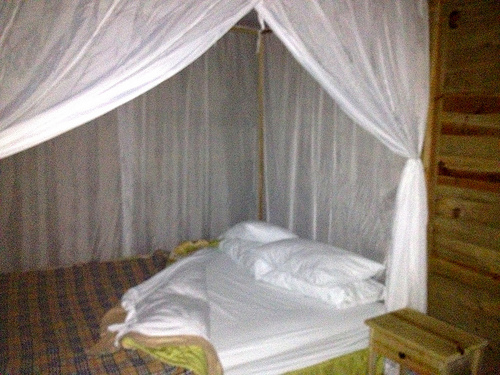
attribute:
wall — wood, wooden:
[420, 0, 499, 373]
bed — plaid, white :
[0, 215, 386, 373]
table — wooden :
[393, 287, 487, 372]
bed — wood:
[6, 236, 445, 344]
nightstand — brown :
[348, 297, 492, 372]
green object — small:
[122, 338, 208, 373]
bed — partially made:
[103, 179, 405, 374]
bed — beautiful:
[9, 185, 390, 374]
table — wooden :
[361, 294, 483, 373]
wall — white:
[245, 141, 318, 196]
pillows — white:
[258, 268, 385, 308]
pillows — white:
[253, 238, 384, 285]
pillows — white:
[218, 218, 298, 242]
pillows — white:
[220, 238, 263, 271]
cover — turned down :
[8, 237, 213, 373]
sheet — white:
[205, 242, 385, 374]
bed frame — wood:
[280, 302, 402, 364]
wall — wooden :
[434, 59, 498, 319]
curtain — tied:
[243, 2, 435, 312]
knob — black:
[398, 350, 407, 360]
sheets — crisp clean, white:
[231, 277, 291, 340]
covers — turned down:
[103, 246, 215, 371]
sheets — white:
[180, 241, 373, 359]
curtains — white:
[1, 0, 436, 315]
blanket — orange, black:
[6, 230, 399, 371]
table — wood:
[365, 299, 490, 373]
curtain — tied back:
[256, 0, 428, 372]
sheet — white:
[156, 250, 242, 330]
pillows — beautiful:
[248, 227, 391, 317]